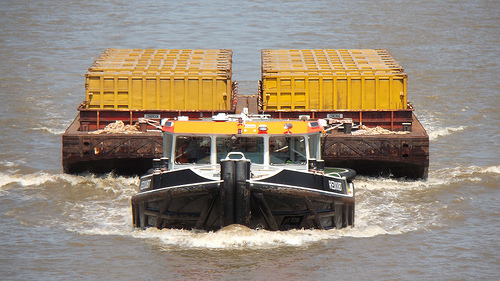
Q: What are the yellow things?
A: Shipping containers.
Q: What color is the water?
A: Brown.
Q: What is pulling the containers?
A: A boat.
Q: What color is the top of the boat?
A: Yellow.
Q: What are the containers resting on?
A: A barge.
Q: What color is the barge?
A: Brown.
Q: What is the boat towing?
A: A barge.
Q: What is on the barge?
A: Containers.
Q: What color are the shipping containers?
A: Yellow.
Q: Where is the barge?
A: In the water.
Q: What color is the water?
A: Brown.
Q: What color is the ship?
A: Black.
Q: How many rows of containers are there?
A: Two.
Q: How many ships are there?
A: One.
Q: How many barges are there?
A: One.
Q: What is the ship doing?
A: Towing the barge.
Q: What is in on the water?
A: A large boat.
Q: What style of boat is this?
A: A barge style.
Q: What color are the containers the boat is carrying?
A: Yellow.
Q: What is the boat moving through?
A: Water.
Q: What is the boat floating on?
A: A body of water.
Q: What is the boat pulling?
A: Containers.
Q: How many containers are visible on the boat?
A: Two.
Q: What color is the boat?
A: Black.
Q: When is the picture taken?
A: Daytime.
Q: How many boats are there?
A: 1.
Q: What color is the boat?
A: Black.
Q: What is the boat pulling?
A: Crates.